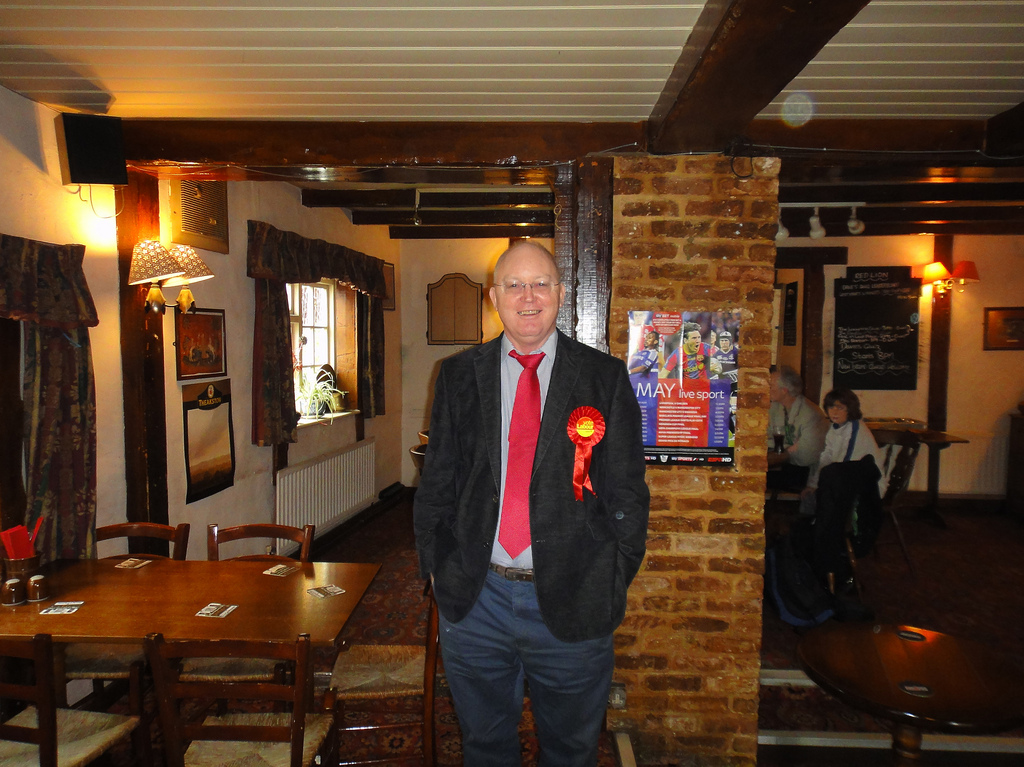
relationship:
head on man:
[489, 241, 567, 353] [412, 239, 654, 763]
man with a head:
[412, 239, 654, 763] [489, 241, 567, 353]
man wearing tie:
[412, 239, 654, 763] [497, 350, 549, 560]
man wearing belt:
[412, 239, 654, 763] [484, 559, 536, 584]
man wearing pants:
[412, 239, 654, 763] [437, 569, 615, 765]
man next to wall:
[412, 239, 654, 763] [604, 153, 785, 765]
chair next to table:
[322, 580, 442, 764] [0, 553, 385, 762]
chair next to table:
[142, 630, 344, 765] [0, 553, 385, 762]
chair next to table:
[0, 630, 145, 762] [0, 553, 385, 762]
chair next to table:
[170, 520, 316, 763] [0, 553, 385, 762]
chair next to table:
[54, 519, 193, 765] [0, 553, 385, 762]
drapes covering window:
[246, 218, 390, 444] [287, 283, 334, 417]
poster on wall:
[627, 309, 744, 465] [604, 153, 785, 765]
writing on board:
[839, 323, 914, 376] [834, 279, 924, 390]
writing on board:
[839, 280, 918, 302] [834, 279, 924, 390]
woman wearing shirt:
[800, 386, 889, 591] [814, 417, 889, 487]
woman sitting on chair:
[800, 386, 889, 591] [837, 431, 925, 572]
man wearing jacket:
[412, 239, 654, 763] [411, 327, 651, 642]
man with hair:
[767, 367, 828, 539] [776, 365, 806, 399]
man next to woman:
[767, 367, 828, 539] [800, 386, 889, 591]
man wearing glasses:
[412, 239, 654, 763] [492, 276, 562, 296]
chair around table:
[322, 580, 442, 764] [0, 553, 385, 762]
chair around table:
[142, 630, 344, 765] [0, 553, 385, 762]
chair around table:
[170, 520, 316, 763] [0, 553, 385, 762]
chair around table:
[54, 519, 193, 765] [0, 553, 385, 762]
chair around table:
[0, 630, 145, 762] [0, 553, 385, 762]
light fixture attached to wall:
[126, 236, 186, 316] [3, 83, 399, 711]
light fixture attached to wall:
[163, 242, 215, 317] [3, 83, 399, 711]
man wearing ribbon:
[412, 239, 654, 763] [566, 402, 609, 500]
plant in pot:
[297, 366, 345, 426] [300, 399, 327, 417]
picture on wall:
[175, 305, 230, 382] [3, 83, 399, 711]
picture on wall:
[181, 376, 238, 506] [3, 83, 399, 711]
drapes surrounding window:
[246, 218, 390, 444] [287, 283, 334, 417]